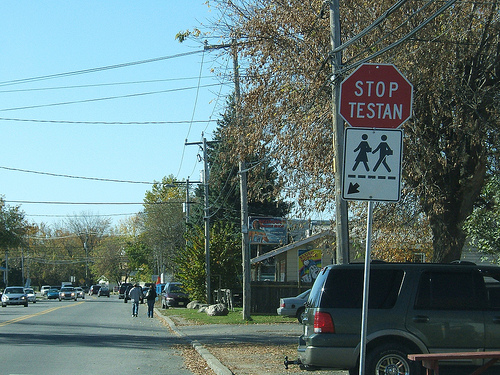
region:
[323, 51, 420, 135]
a stop sign on a pole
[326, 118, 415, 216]
a black and white crossing sign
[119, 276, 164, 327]
two people walking down the street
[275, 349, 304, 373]
a trailer hitch on the back of SUV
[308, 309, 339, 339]
the red tail light on an SUV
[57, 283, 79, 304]
a car with its headlights on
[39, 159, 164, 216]
two power lines over a street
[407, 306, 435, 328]
the door handle on an SUV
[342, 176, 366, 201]
a black arrow on a white sign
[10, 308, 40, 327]
yellow lines painted on the road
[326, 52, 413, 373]
street sign on pole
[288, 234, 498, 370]
car parked on driveway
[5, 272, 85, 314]
cars on the street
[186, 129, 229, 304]
utility poles on the sidewalk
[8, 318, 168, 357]
shadow casted on the ground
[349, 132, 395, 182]
image of pedestrians on sign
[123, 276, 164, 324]
people walking in the street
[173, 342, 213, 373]
leaves on the street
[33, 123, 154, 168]
blue sky in the distance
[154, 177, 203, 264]
green leaves on a tree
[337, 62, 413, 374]
Two signs attached to a metal pole.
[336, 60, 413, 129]
A red sign with white letters.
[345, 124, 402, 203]
A white sign with black writing on the front.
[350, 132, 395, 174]
Black image of people walking on the white sign.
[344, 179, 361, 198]
Black arrow pointing downward on the white sign.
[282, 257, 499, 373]
Sports utility vehicle with a hitch on the back.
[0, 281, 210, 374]
Cars being driven on a paved road.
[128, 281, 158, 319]
People walking on the side of the road.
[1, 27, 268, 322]
Wooden poles with powerlines.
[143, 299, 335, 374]
Brown tree leaves on the ground.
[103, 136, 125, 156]
Small part of the light blue sky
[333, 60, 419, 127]
Red and white stop sign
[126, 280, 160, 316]
Two pedestrians walking on the street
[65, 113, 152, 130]
Single power line in the air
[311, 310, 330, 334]
Back headlight of vehicle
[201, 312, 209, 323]
Tiny patch of green grass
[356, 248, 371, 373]
Silver pole that is connected to pedestrian crosswalk and stop sign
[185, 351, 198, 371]
Dead leaves on the street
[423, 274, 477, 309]
Side window of the car